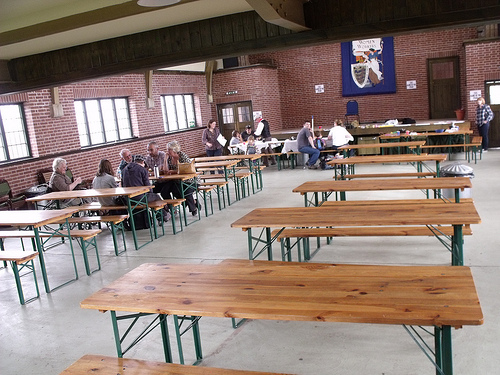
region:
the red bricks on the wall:
[0, 20, 498, 200]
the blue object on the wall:
[339, 33, 396, 97]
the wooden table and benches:
[0, 128, 482, 373]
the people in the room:
[48, 97, 493, 217]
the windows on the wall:
[0, 90, 198, 162]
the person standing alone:
[476, 95, 493, 150]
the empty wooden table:
[80, 262, 482, 374]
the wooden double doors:
[215, 100, 253, 155]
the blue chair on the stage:
[344, 99, 361, 125]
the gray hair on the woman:
[165, 139, 179, 152]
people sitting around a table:
[37, 136, 214, 236]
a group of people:
[187, 98, 284, 175]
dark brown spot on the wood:
[294, 278, 306, 289]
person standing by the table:
[249, 108, 274, 166]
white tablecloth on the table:
[224, 135, 314, 158]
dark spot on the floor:
[294, 350, 308, 364]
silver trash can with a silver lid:
[435, 158, 480, 213]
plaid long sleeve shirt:
[470, 101, 497, 126]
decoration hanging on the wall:
[339, 35, 403, 99]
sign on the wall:
[311, 80, 330, 97]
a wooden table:
[77, 268, 476, 342]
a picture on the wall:
[339, 64, 396, 93]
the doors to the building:
[217, 104, 249, 140]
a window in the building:
[73, 98, 131, 134]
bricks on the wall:
[288, 72, 324, 131]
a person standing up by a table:
[471, 94, 496, 145]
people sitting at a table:
[48, 150, 199, 210]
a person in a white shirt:
[323, 115, 348, 139]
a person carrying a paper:
[199, 118, 226, 155]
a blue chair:
[341, 95, 359, 121]